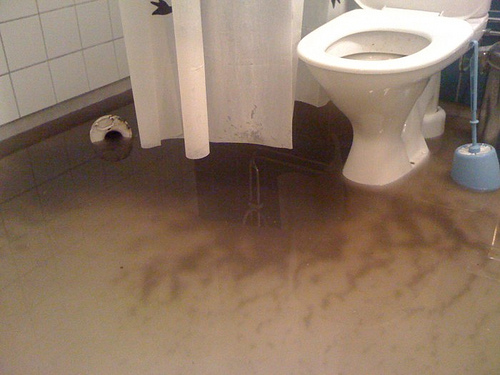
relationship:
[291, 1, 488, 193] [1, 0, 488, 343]
toilet in bathroom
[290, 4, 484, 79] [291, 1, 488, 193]
seat on toilet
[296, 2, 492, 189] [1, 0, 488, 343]
white toilet in bathroom